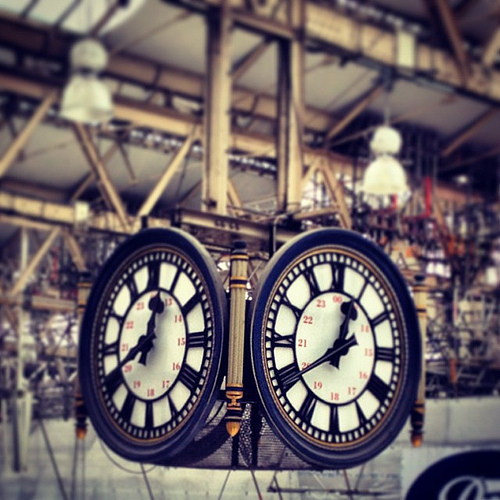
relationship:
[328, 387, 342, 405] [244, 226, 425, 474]
18 on clock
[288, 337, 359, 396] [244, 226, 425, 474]
minute hand of clock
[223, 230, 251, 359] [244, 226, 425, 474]
pillar for clock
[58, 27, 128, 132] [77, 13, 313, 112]
light on ceiling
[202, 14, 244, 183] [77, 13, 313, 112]
beam on ceiling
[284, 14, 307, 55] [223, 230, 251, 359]
bands on pillar